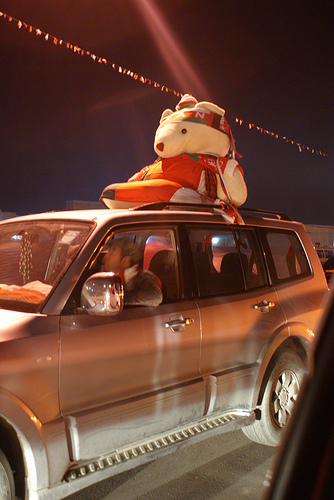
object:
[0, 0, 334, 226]
sky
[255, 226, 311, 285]
window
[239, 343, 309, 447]
tire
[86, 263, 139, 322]
mirror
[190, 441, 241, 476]
ground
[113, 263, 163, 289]
scarf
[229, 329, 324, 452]
tire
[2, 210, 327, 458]
car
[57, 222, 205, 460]
side door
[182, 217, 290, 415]
side door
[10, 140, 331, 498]
car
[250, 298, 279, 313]
handle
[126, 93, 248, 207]
teddy bear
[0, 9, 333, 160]
banner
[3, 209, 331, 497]
car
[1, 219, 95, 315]
vehicle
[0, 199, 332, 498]
windshield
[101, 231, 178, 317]
man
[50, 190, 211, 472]
driver door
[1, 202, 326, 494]
vehicle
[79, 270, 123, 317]
mirror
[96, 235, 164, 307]
person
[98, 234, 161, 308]
man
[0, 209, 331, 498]
suv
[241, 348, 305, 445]
tire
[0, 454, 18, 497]
tire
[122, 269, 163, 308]
coat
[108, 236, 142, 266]
hat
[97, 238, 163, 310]
man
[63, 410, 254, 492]
running board